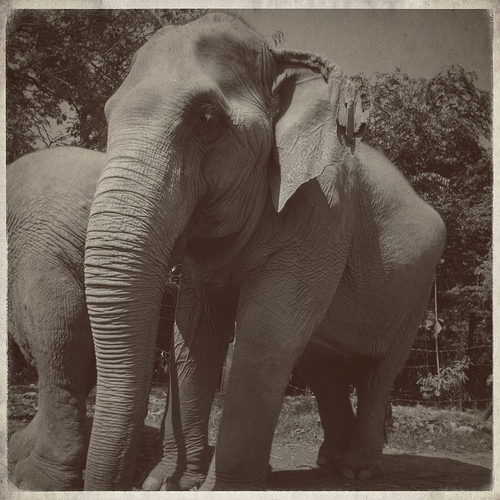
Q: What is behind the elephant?
A: Trees.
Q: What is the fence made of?
A: Wire.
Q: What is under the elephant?
A: Ground.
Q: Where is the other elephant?
A: On the left.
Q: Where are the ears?
A: On the elephant.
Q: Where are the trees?
A: Behind the elephant.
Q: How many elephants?
A: 2.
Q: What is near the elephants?
A: Trees.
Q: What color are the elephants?
A: Gray.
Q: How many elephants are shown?
A: 2.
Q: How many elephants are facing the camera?
A: 1.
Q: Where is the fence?
A: Behind the elephants.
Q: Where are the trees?
A: Behind the fence.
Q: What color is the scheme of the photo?
A: Black and white.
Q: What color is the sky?
A: Grey.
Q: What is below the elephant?
A: Shadow.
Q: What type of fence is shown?
A: Barbed wire.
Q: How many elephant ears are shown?
A: 1.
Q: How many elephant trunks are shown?
A: 1.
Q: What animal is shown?
A: Elephant.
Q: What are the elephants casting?
A: Shadows on the ground.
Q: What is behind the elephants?
A: Trees.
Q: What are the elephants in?
A: Pen.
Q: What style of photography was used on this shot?
A: Black and white.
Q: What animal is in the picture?
A: Elephants.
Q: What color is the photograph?
A: Black and grey.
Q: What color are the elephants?
A: Grey.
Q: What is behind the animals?
A: Trees.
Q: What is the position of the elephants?
A: They are standing head to toe.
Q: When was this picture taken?
A: Daytime.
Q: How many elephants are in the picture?
A: 2.